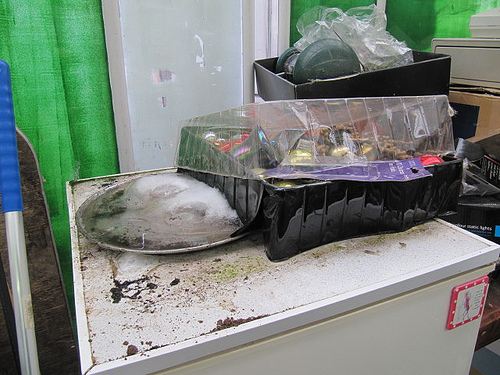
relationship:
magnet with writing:
[440, 285, 495, 332] [475, 283, 484, 313]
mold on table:
[76, 172, 252, 254] [76, 185, 490, 374]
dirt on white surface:
[109, 268, 172, 304] [71, 160, 496, 370]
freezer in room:
[55, 180, 497, 348] [0, 0, 494, 374]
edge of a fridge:
[350, 224, 481, 282] [78, 252, 495, 373]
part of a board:
[65, 327, 102, 367] [154, 260, 496, 374]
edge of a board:
[443, 288, 458, 330] [442, 273, 489, 330]